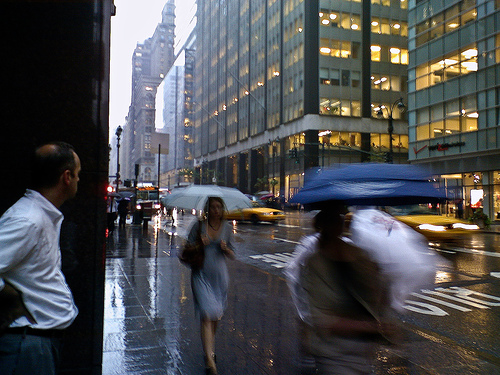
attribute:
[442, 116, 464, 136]
window — glass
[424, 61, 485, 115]
window — glass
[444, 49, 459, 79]
window — glass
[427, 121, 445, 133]
window — glass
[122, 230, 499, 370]
ground — wet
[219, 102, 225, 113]
window — glass